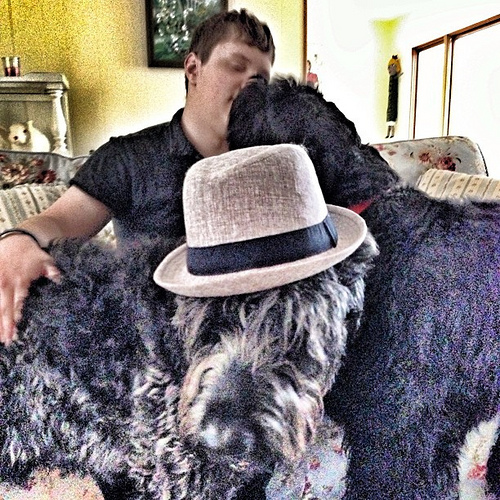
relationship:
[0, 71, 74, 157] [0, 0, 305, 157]
shelf by wall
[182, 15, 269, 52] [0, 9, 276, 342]
brown hair on guy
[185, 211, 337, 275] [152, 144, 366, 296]
black ring around a grey hat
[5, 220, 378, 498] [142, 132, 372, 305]
dog with hat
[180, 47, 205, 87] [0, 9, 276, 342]
ear right guy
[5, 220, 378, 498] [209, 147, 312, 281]
dog wearing hat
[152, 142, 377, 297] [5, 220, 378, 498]
hat on dog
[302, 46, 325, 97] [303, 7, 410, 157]
poster on wall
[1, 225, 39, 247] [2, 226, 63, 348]
band on hand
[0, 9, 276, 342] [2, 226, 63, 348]
guy has hand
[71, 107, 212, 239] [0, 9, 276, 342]
shirt on guy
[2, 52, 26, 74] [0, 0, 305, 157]
candle on wall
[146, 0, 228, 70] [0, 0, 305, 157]
picture on wall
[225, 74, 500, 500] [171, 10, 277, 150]
dog kisses man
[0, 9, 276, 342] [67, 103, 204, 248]
guy wears shirt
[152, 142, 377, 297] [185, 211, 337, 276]
hat has black ring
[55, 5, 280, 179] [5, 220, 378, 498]
guy has dog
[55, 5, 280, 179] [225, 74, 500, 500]
guy has dog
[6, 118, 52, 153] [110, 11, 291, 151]
bunny behind guy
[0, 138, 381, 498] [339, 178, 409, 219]
dog has collar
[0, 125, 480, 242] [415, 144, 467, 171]
couch has floral pattern